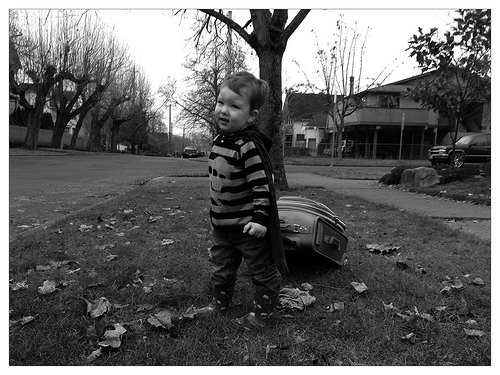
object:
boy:
[193, 72, 283, 330]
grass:
[10, 177, 490, 365]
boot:
[195, 282, 234, 313]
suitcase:
[275, 197, 348, 267]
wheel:
[343, 258, 350, 270]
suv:
[428, 135, 492, 167]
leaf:
[98, 324, 129, 349]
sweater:
[208, 131, 270, 228]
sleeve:
[239, 140, 270, 227]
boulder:
[401, 167, 439, 188]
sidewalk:
[284, 172, 490, 238]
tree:
[9, 8, 97, 147]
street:
[10, 151, 204, 241]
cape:
[226, 125, 288, 280]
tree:
[173, 8, 310, 189]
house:
[326, 64, 492, 158]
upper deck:
[333, 65, 490, 125]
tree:
[403, 9, 492, 178]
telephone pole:
[165, 102, 173, 157]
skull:
[209, 155, 231, 198]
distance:
[83, 75, 200, 176]